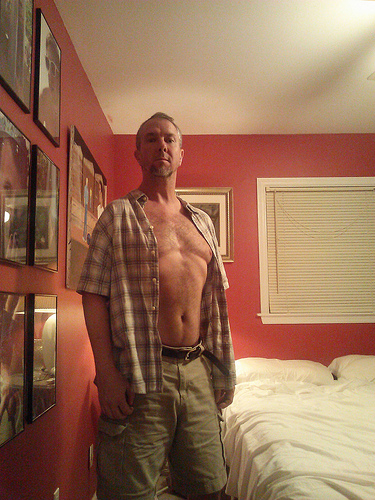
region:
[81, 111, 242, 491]
this is a person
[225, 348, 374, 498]
this is a bed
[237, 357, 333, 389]
this is a pillow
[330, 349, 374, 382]
this is a pillow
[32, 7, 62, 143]
this is a picture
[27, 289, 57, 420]
this is a picture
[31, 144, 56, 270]
this is a picture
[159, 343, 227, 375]
this is a belt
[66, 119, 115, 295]
this is a picture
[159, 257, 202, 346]
this is a stomach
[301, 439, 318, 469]
part of a sheet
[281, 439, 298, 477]
part f a bed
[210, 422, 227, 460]
part of a pocket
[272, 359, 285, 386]
part of a pillow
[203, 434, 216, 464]
part fo a line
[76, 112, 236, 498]
A man standing by a bed in a bedroom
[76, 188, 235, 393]
The plaid shirt the man is wearing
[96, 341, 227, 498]
Khaki shorts the man is wearing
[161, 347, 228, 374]
Brown leather belt around the man's waist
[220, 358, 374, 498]
White bed sheets on the bed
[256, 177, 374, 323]
A white window frame with white blinds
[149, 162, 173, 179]
Short beard the man is sporting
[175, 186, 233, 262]
A painting frame on the wall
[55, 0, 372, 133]
White ceiling visible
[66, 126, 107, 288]
A picture frame on the wall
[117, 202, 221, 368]
a man with his shirt unbuttoned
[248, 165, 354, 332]
a window covered with a mini blind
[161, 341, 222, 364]
a man wearing a brown belt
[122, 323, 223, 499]
a man wearing shorts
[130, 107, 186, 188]
a man with facial hair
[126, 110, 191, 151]
a man with grey hair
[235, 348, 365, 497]
white sheets and pillows on a bed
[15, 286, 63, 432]
a picture hanging on a wall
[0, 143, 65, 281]
two pictures hanging on a wall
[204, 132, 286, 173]
a wall painted red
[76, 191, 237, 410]
Man wearing unbuttoned shirt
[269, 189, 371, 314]
Blinds on the window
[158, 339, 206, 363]
Belt around man's waist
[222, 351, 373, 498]
Bed with white sheets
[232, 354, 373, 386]
Pillows on the bed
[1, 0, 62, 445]
Framed photos on the wall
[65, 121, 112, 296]
Drawing on the wall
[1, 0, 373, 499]
Walls painted pink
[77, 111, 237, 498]
Man wearing plaid opened shirt and khaki shorts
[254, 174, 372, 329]
Window with blind drawn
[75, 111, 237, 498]
scary man standing with his shirt unbuttoned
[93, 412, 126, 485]
velcro pocket on side of shorts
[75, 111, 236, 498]
man wearing unbuttoned plaid shirt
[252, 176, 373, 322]
white wood frame with white blinds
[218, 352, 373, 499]
messy bed with white sheet and pillow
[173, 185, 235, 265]
artwork inside of gold frame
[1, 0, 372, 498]
scary man in bedroom with red walls